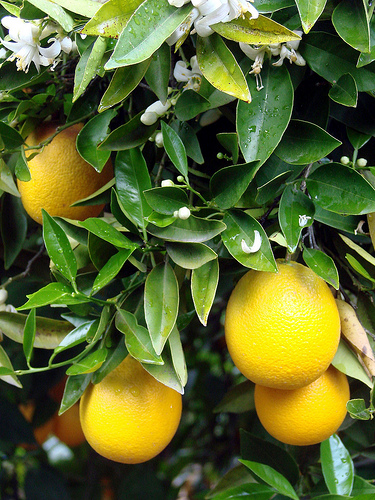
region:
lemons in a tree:
[3, 6, 372, 496]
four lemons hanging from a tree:
[4, 103, 361, 473]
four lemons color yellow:
[8, 111, 373, 486]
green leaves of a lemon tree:
[91, 121, 353, 257]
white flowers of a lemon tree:
[0, 0, 311, 98]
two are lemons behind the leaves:
[6, 375, 87, 458]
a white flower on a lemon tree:
[5, 14, 66, 84]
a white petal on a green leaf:
[232, 224, 277, 273]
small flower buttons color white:
[151, 164, 207, 226]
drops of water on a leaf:
[232, 98, 284, 163]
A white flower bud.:
[170, 206, 192, 221]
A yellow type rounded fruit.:
[224, 257, 342, 389]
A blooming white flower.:
[1, 16, 74, 73]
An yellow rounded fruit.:
[77, 353, 181, 461]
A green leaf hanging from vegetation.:
[235, 452, 301, 499]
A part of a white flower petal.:
[237, 230, 268, 258]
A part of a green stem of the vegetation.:
[21, 96, 103, 159]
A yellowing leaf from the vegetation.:
[331, 293, 373, 381]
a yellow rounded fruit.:
[11, 125, 118, 221]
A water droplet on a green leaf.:
[336, 451, 348, 467]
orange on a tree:
[219, 256, 348, 390]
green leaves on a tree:
[145, 248, 220, 355]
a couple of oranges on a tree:
[219, 252, 370, 462]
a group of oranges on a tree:
[3, 253, 358, 472]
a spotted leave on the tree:
[342, 297, 374, 378]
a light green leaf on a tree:
[7, 313, 72, 352]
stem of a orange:
[278, 246, 301, 265]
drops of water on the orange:
[109, 378, 149, 406]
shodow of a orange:
[246, 383, 325, 424]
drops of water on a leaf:
[331, 439, 357, 492]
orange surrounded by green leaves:
[11, 91, 116, 235]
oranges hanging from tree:
[77, 250, 347, 461]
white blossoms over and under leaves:
[7, 9, 297, 76]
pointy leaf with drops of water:
[40, 205, 74, 276]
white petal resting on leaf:
[227, 212, 273, 267]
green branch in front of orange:
[22, 109, 97, 147]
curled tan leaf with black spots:
[335, 295, 369, 375]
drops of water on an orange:
[108, 380, 138, 395]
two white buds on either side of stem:
[338, 153, 363, 162]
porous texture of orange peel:
[31, 155, 80, 192]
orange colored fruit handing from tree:
[227, 255, 323, 393]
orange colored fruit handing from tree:
[265, 377, 344, 447]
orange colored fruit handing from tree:
[101, 353, 171, 455]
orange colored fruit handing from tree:
[19, 129, 91, 224]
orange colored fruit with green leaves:
[72, 325, 176, 472]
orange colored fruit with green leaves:
[19, 117, 137, 244]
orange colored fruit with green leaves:
[223, 228, 320, 376]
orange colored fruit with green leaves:
[245, 372, 371, 436]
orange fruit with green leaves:
[82, 357, 179, 473]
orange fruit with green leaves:
[227, 245, 331, 385]